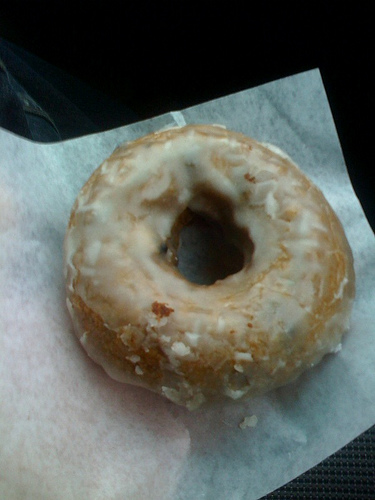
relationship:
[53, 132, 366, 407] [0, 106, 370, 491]
donut on paper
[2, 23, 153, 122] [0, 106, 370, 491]
jeans under paper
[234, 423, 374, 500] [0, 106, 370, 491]
seat under paper